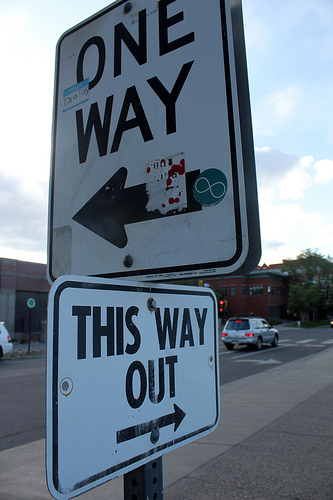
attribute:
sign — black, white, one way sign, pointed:
[45, 0, 262, 278]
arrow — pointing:
[68, 151, 228, 243]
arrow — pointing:
[111, 401, 210, 449]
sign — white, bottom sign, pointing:
[47, 282, 228, 487]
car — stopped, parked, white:
[217, 314, 283, 353]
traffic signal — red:
[219, 296, 227, 319]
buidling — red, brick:
[218, 258, 315, 320]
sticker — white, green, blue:
[191, 166, 225, 212]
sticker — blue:
[62, 80, 87, 113]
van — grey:
[2, 321, 18, 359]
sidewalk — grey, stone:
[2, 347, 332, 493]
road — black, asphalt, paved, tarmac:
[0, 318, 332, 448]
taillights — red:
[221, 327, 258, 339]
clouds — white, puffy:
[262, 160, 333, 267]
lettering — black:
[68, 0, 210, 178]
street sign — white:
[47, 0, 246, 281]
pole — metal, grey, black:
[118, 455, 169, 497]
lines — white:
[240, 336, 317, 367]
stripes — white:
[279, 331, 329, 353]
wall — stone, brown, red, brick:
[1, 262, 50, 349]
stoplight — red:
[217, 295, 226, 314]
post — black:
[219, 286, 228, 325]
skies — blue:
[2, 3, 333, 265]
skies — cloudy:
[263, 97, 333, 256]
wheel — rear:
[251, 338, 267, 348]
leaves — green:
[286, 273, 324, 307]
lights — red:
[216, 298, 225, 314]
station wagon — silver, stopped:
[221, 313, 281, 354]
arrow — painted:
[234, 352, 287, 368]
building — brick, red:
[213, 253, 330, 324]